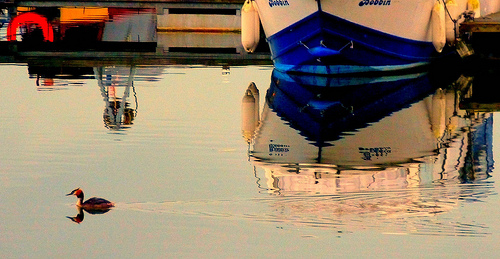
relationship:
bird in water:
[35, 157, 171, 239] [33, 64, 498, 251]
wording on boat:
[260, 0, 295, 8] [239, 2, 461, 103]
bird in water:
[64, 187, 115, 208] [3, 58, 499, 257]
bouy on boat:
[240, 0, 256, 52] [239, 1, 479, 78]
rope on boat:
[442, 5, 468, 39] [245, 2, 487, 83]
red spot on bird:
[75, 186, 83, 197] [64, 187, 115, 208]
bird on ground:
[64, 187, 115, 208] [16, 95, 306, 256]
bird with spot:
[64, 187, 115, 208] [70, 185, 83, 197]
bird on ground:
[64, 187, 115, 208] [32, 24, 152, 58]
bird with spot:
[64, 187, 115, 208] [69, 185, 84, 195]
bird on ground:
[64, 187, 115, 208] [38, 20, 490, 250]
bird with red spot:
[64, 187, 115, 208] [74, 190, 79, 195]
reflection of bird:
[62, 206, 115, 225] [63, 180, 115, 204]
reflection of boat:
[261, 106, 450, 170] [254, 5, 444, 68]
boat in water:
[236, 1, 499, 73] [231, 155, 341, 256]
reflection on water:
[90, 62, 140, 133] [210, 170, 324, 256]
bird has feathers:
[64, 187, 115, 208] [55, 181, 158, 236]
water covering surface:
[3, 58, 499, 257] [124, 159, 478, 256]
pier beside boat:
[453, 5, 483, 72] [247, 0, 474, 71]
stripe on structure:
[150, 14, 245, 56] [125, 3, 282, 51]